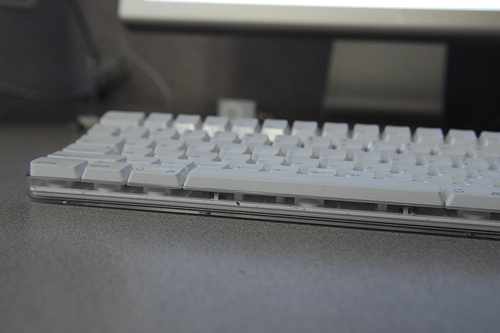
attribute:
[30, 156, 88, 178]
key — white, ctrl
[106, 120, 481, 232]
keyboard — white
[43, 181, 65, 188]
pad — round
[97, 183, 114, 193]
pad — round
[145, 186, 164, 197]
pad — round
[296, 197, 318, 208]
pad — round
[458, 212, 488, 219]
pad — round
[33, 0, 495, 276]
computer — black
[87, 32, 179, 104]
wires — blurry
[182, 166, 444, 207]
spacebar — long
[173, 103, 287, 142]
light — shining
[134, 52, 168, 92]
wires — blurry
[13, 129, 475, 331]
table — grey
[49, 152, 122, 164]
shift key — keyboard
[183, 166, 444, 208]
bar — long, short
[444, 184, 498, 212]
bar — long, short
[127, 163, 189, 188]
bar — long, short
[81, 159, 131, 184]
bar — long, short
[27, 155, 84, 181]
bar — long, short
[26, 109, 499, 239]
keyboard — white, clear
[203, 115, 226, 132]
key — white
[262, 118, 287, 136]
key — white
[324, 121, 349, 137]
key — white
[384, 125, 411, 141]
key — white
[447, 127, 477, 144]
key — white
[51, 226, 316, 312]
table — grey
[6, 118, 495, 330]
surface — gray, speckled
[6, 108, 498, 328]
table — grey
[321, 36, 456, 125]
stand — silver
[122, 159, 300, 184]
keys —  bottom row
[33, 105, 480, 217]
keyboard — white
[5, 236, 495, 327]
table — grey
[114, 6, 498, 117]
monitor — silver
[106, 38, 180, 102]
cords — white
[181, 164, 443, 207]
space bar — white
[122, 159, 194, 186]
button — white, plastic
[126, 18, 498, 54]
edge — dark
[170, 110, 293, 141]
light — shining